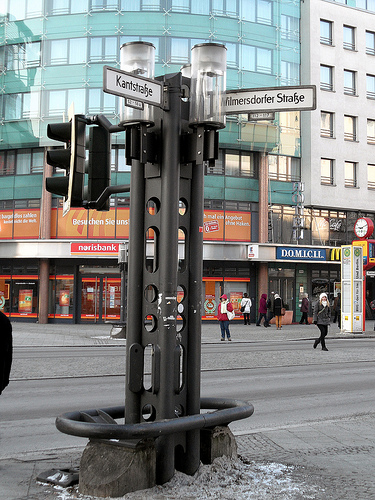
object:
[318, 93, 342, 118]
ground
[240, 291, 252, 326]
people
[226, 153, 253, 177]
windows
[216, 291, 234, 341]
person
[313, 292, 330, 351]
person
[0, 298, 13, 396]
person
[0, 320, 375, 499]
road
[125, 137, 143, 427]
pole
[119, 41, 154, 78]
street light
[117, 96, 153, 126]
street light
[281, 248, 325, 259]
building sign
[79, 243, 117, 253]
building sign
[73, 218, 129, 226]
building sign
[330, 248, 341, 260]
logo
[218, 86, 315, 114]
sign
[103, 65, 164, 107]
sign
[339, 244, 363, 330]
sign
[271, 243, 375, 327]
business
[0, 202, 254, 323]
business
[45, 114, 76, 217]
light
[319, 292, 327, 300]
hat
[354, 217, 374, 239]
clock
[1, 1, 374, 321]
building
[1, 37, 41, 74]
windows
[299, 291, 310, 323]
person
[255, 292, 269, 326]
person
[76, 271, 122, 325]
windows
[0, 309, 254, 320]
border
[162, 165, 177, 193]
metal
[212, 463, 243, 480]
snow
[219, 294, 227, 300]
hat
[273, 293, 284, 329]
person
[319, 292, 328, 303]
head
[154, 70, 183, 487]
pole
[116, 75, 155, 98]
foreign language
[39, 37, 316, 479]
metal contraption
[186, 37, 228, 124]
light